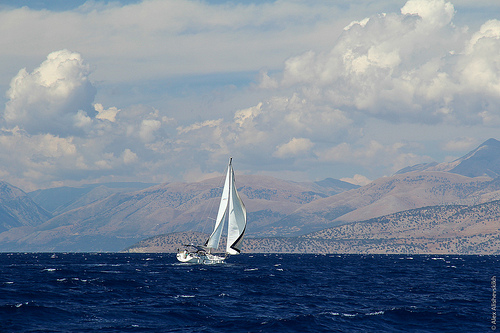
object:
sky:
[0, 0, 499, 190]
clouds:
[93, 105, 120, 121]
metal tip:
[228, 157, 232, 165]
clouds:
[2, 48, 95, 129]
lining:
[202, 163, 229, 249]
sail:
[225, 166, 247, 256]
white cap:
[48, 267, 58, 271]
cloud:
[398, 0, 456, 31]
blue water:
[0, 252, 500, 333]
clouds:
[469, 35, 499, 60]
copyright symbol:
[490, 276, 497, 332]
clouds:
[271, 137, 319, 160]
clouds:
[354, 88, 424, 124]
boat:
[175, 156, 248, 265]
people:
[201, 253, 206, 256]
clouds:
[371, 51, 404, 68]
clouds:
[138, 118, 162, 144]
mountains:
[449, 137, 500, 164]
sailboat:
[175, 156, 248, 266]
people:
[185, 250, 188, 258]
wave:
[39, 268, 79, 276]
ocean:
[0, 252, 500, 333]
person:
[180, 250, 183, 254]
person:
[189, 252, 193, 257]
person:
[177, 248, 179, 254]